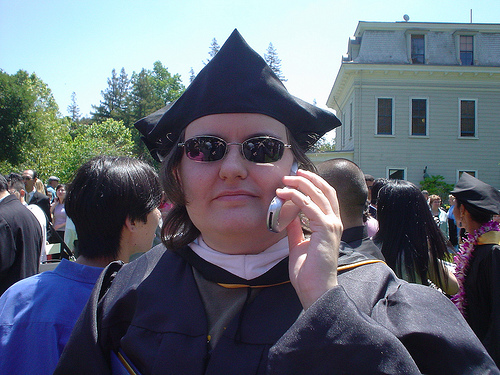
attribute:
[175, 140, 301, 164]
sunglasses — sun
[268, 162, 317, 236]
cellphone — cell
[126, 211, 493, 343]
robe — black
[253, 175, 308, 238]
cell phone — silver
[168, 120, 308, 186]
sunglasses — sun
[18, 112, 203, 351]
person — black-haired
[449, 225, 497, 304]
lae — decorative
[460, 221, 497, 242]
neck — person's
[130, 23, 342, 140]
cap — black